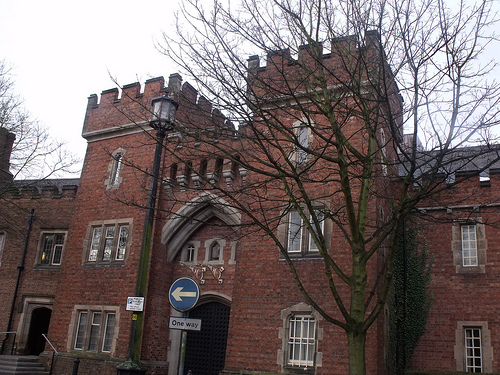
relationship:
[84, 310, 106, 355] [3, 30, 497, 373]
window on building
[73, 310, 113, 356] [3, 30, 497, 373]
window on building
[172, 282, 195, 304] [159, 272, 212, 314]
aarow on sign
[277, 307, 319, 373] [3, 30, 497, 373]
window on building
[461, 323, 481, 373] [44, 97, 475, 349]
window on building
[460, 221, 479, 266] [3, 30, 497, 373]
window on building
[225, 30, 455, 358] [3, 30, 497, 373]
tree on building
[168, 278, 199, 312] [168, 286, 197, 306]
aarow with arrow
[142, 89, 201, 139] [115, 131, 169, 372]
light on top of lamp post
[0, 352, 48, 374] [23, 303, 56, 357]
stairs leading to door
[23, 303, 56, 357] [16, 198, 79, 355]
door in a brick wall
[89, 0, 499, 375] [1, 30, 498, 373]
tree in front of armory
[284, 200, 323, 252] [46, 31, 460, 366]
window on building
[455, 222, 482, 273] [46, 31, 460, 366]
window on building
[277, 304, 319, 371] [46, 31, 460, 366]
window on building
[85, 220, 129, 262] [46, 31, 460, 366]
window on building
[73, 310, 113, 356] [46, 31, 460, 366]
window on building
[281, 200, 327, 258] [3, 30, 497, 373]
window on building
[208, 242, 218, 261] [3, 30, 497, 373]
window on building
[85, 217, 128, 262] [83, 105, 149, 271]
window on building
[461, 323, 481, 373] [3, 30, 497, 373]
window on building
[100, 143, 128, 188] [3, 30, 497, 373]
window on building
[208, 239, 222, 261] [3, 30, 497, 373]
window on building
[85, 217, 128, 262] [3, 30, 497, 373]
window on building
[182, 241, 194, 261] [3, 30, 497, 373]
window on building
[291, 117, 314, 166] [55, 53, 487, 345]
window on building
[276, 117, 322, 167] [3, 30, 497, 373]
window on building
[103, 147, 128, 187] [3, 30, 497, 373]
window on building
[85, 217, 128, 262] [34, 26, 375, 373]
window on a building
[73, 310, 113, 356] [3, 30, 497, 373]
window on a building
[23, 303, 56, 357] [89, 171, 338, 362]
door to a building